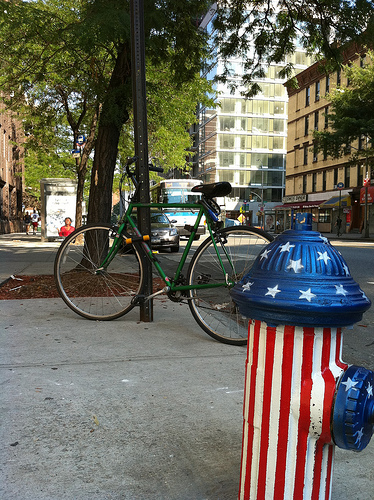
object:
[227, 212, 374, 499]
fire hydrant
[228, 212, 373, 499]
american flag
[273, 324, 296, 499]
stripe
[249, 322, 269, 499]
stripe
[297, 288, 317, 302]
star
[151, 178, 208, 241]
bus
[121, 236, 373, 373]
street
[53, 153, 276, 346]
bike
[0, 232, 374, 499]
sidewalk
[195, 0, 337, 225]
building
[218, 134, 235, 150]
window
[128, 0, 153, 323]
pole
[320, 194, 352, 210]
awning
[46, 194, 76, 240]
sign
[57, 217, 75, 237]
woman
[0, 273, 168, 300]
mulch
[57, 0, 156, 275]
tree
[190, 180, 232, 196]
seat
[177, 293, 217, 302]
kickstand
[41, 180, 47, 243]
sign pole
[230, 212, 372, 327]
top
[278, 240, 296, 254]
star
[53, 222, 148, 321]
tire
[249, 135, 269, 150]
window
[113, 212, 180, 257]
car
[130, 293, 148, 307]
pedal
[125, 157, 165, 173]
handlebars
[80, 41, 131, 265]
trunk